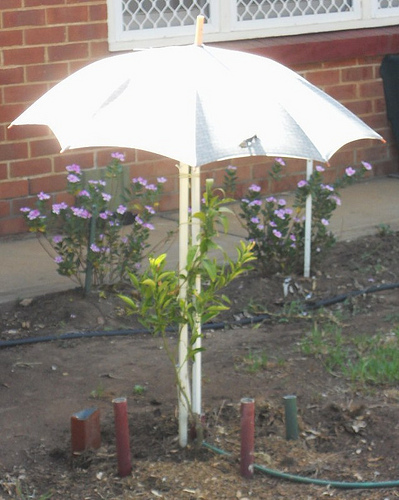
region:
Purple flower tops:
[30, 173, 139, 253]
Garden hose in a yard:
[201, 444, 379, 494]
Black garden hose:
[15, 284, 384, 340]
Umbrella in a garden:
[78, 26, 348, 189]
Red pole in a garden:
[106, 391, 139, 481]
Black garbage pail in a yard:
[380, 58, 393, 109]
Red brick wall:
[11, 147, 60, 182]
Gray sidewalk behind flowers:
[13, 218, 157, 278]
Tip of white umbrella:
[190, 13, 209, 51]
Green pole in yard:
[280, 385, 308, 451]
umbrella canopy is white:
[7, 43, 386, 170]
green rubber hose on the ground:
[198, 434, 398, 488]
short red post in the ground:
[239, 397, 260, 475]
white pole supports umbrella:
[175, 163, 189, 446]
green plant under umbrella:
[114, 177, 266, 451]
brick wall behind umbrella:
[0, 1, 397, 233]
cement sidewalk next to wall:
[0, 177, 398, 304]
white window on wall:
[106, 0, 397, 45]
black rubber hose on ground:
[0, 279, 398, 345]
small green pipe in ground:
[281, 393, 306, 437]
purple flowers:
[48, 198, 130, 243]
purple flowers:
[237, 181, 300, 240]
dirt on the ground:
[48, 340, 129, 390]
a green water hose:
[276, 463, 392, 495]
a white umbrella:
[69, 134, 224, 160]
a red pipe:
[234, 401, 267, 472]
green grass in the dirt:
[311, 329, 398, 366]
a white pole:
[175, 202, 205, 255]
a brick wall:
[13, 148, 58, 180]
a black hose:
[43, 328, 150, 342]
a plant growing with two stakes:
[146, 144, 236, 451]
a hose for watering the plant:
[195, 430, 397, 494]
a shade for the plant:
[6, 36, 390, 177]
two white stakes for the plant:
[173, 160, 209, 452]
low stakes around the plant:
[104, 389, 304, 481]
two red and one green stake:
[107, 388, 311, 478]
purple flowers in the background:
[17, 151, 163, 283]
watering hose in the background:
[206, 279, 397, 330]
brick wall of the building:
[0, 3, 96, 94]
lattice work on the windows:
[103, 0, 396, 40]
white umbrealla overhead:
[104, 65, 350, 177]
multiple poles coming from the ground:
[76, 376, 325, 454]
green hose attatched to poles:
[262, 449, 326, 498]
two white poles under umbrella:
[156, 186, 241, 473]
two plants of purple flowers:
[55, 165, 349, 291]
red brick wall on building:
[38, 26, 93, 58]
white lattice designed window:
[140, 0, 345, 44]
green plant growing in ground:
[164, 174, 245, 394]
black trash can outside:
[360, 58, 397, 86]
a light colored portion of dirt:
[173, 463, 229, 497]